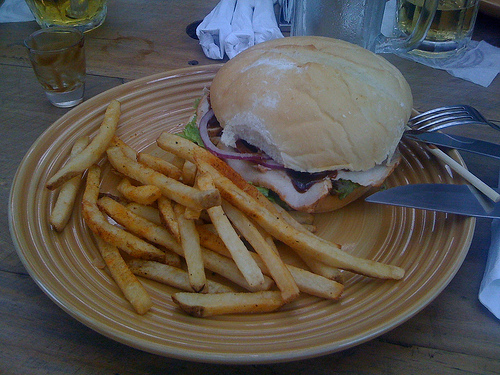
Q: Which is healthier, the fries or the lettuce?
A: The lettuce is healthier than the fries.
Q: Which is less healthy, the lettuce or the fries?
A: The fries is less healthy than the lettuce.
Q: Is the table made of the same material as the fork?
A: No, the table is made of wood and the fork is made of metal.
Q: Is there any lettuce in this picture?
A: Yes, there is lettuce.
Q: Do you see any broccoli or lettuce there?
A: Yes, there is lettuce.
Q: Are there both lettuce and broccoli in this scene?
A: No, there is lettuce but no broccoli.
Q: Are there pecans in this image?
A: No, there are no pecans.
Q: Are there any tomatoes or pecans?
A: No, there are no pecans or tomatoes.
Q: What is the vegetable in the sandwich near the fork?
A: The vegetable is lettuce.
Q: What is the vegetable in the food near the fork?
A: The vegetable is lettuce.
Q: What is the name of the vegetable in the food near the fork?
A: The vegetable is lettuce.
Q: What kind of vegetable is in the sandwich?
A: The vegetable is lettuce.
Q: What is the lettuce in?
A: The lettuce is in the sandwich.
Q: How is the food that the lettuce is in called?
A: The food is a sandwich.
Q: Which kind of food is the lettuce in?
A: The lettuce is in the sandwich.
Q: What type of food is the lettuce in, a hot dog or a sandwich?
A: The lettuce is in a sandwich.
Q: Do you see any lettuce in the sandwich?
A: Yes, there is lettuce in the sandwich.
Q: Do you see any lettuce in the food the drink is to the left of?
A: Yes, there is lettuce in the sandwich.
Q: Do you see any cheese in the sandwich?
A: No, there is lettuce in the sandwich.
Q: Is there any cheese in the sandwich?
A: No, there is lettuce in the sandwich.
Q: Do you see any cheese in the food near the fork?
A: No, there is lettuce in the sandwich.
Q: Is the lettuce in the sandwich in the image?
A: Yes, the lettuce is in the sandwich.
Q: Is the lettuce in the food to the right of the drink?
A: Yes, the lettuce is in the sandwich.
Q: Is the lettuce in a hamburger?
A: No, the lettuce is in the sandwich.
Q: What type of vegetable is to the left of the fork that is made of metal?
A: The vegetable is lettuce.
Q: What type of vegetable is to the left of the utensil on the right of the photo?
A: The vegetable is lettuce.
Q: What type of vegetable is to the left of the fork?
A: The vegetable is lettuce.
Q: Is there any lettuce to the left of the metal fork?
A: Yes, there is lettuce to the left of the fork.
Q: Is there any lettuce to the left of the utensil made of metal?
A: Yes, there is lettuce to the left of the fork.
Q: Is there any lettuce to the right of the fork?
A: No, the lettuce is to the left of the fork.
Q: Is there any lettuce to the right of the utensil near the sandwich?
A: No, the lettuce is to the left of the fork.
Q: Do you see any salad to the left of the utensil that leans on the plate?
A: No, there is lettuce to the left of the fork.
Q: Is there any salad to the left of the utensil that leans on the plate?
A: No, there is lettuce to the left of the fork.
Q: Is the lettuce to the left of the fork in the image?
A: Yes, the lettuce is to the left of the fork.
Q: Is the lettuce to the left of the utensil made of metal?
A: Yes, the lettuce is to the left of the fork.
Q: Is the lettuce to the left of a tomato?
A: No, the lettuce is to the left of the fork.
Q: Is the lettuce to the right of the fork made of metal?
A: No, the lettuce is to the left of the fork.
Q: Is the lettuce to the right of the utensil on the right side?
A: No, the lettuce is to the left of the fork.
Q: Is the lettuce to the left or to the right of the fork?
A: The lettuce is to the left of the fork.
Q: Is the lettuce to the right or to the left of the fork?
A: The lettuce is to the left of the fork.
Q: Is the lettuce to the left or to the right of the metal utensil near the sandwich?
A: The lettuce is to the left of the fork.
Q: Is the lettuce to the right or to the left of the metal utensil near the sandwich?
A: The lettuce is to the left of the fork.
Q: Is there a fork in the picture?
A: Yes, there is a fork.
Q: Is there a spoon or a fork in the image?
A: Yes, there is a fork.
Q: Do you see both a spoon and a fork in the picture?
A: No, there is a fork but no spoons.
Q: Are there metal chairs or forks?
A: Yes, there is a metal fork.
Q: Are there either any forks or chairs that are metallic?
A: Yes, the fork is metallic.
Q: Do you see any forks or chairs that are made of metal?
A: Yes, the fork is made of metal.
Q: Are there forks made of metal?
A: Yes, there is a fork that is made of metal.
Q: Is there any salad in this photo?
A: No, there is no salad.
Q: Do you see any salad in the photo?
A: No, there is no salad.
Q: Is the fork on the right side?
A: Yes, the fork is on the right of the image.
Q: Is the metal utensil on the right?
A: Yes, the fork is on the right of the image.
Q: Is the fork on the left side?
A: No, the fork is on the right of the image.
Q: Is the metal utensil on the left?
A: No, the fork is on the right of the image.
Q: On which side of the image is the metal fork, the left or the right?
A: The fork is on the right of the image.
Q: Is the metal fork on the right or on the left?
A: The fork is on the right of the image.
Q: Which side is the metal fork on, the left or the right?
A: The fork is on the right of the image.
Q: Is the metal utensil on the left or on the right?
A: The fork is on the right of the image.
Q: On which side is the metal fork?
A: The fork is on the right of the image.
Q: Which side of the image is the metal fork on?
A: The fork is on the right of the image.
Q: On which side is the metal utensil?
A: The fork is on the right of the image.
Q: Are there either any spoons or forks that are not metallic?
A: No, there is a fork but it is metallic.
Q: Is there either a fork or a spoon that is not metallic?
A: No, there is a fork but it is metallic.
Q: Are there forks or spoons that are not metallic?
A: No, there is a fork but it is metallic.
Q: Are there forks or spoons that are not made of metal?
A: No, there is a fork but it is made of metal.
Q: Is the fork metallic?
A: Yes, the fork is metallic.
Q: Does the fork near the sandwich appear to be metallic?
A: Yes, the fork is metallic.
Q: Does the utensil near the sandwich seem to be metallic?
A: Yes, the fork is metallic.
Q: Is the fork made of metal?
A: Yes, the fork is made of metal.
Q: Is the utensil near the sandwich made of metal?
A: Yes, the fork is made of metal.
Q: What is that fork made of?
A: The fork is made of metal.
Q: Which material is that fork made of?
A: The fork is made of metal.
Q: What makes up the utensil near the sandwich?
A: The fork is made of metal.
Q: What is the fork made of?
A: The fork is made of metal.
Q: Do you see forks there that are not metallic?
A: No, there is a fork but it is metallic.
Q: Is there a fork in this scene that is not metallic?
A: No, there is a fork but it is metallic.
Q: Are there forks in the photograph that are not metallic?
A: No, there is a fork but it is metallic.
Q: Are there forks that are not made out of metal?
A: No, there is a fork but it is made of metal.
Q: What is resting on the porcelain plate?
A: The fork is resting on the plate.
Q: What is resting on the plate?
A: The fork is resting on the plate.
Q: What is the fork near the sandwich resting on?
A: The fork is resting on the plate.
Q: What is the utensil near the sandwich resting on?
A: The fork is resting on the plate.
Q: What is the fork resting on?
A: The fork is resting on the plate.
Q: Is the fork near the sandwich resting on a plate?
A: Yes, the fork is resting on a plate.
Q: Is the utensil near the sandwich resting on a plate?
A: Yes, the fork is resting on a plate.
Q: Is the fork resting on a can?
A: No, the fork is resting on a plate.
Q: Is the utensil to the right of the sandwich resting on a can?
A: No, the fork is resting on a plate.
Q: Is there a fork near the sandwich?
A: Yes, there is a fork near the sandwich.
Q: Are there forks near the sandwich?
A: Yes, there is a fork near the sandwich.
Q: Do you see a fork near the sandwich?
A: Yes, there is a fork near the sandwich.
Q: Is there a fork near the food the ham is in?
A: Yes, there is a fork near the sandwich.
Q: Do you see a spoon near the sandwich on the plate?
A: No, there is a fork near the sandwich.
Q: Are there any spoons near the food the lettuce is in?
A: No, there is a fork near the sandwich.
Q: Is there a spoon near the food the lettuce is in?
A: No, there is a fork near the sandwich.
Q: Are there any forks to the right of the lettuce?
A: Yes, there is a fork to the right of the lettuce.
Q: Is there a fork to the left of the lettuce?
A: No, the fork is to the right of the lettuce.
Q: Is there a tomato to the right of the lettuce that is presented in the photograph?
A: No, there is a fork to the right of the lettuce.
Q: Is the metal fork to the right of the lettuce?
A: Yes, the fork is to the right of the lettuce.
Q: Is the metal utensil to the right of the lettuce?
A: Yes, the fork is to the right of the lettuce.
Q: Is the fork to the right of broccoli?
A: No, the fork is to the right of the lettuce.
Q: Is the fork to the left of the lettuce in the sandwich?
A: No, the fork is to the right of the lettuce.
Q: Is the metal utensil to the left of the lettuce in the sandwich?
A: No, the fork is to the right of the lettuce.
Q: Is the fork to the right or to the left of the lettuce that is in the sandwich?
A: The fork is to the right of the lettuce.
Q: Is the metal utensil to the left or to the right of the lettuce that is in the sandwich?
A: The fork is to the right of the lettuce.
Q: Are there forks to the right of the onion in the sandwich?
A: Yes, there is a fork to the right of the onion.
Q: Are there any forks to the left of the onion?
A: No, the fork is to the right of the onion.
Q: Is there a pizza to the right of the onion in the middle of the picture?
A: No, there is a fork to the right of the onion.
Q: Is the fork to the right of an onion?
A: Yes, the fork is to the right of an onion.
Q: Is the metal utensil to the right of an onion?
A: Yes, the fork is to the right of an onion.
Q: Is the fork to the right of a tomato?
A: No, the fork is to the right of an onion.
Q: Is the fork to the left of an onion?
A: No, the fork is to the right of an onion.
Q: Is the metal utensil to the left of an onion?
A: No, the fork is to the right of an onion.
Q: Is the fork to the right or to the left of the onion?
A: The fork is to the right of the onion.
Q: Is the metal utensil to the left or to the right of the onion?
A: The fork is to the right of the onion.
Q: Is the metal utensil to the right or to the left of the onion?
A: The fork is to the right of the onion.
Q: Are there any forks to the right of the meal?
A: Yes, there is a fork to the right of the meal.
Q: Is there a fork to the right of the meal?
A: Yes, there is a fork to the right of the meal.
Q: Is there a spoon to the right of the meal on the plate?
A: No, there is a fork to the right of the meal.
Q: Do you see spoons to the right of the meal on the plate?
A: No, there is a fork to the right of the meal.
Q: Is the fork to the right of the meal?
A: Yes, the fork is to the right of the meal.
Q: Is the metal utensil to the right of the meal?
A: Yes, the fork is to the right of the meal.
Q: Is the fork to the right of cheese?
A: No, the fork is to the right of the meal.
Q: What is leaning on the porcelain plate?
A: The fork is leaning on the plate.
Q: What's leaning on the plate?
A: The fork is leaning on the plate.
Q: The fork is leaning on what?
A: The fork is leaning on the plate.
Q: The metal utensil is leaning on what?
A: The fork is leaning on the plate.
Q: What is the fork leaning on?
A: The fork is leaning on the plate.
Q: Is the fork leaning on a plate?
A: Yes, the fork is leaning on a plate.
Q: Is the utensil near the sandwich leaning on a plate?
A: Yes, the fork is leaning on a plate.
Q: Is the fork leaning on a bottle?
A: No, the fork is leaning on a plate.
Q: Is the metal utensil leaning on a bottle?
A: No, the fork is leaning on a plate.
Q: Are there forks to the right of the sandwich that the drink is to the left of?
A: Yes, there is a fork to the right of the sandwich.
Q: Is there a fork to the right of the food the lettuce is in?
A: Yes, there is a fork to the right of the sandwich.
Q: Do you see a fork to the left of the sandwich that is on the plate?
A: No, the fork is to the right of the sandwich.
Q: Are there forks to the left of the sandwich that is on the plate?
A: No, the fork is to the right of the sandwich.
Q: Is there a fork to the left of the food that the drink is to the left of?
A: No, the fork is to the right of the sandwich.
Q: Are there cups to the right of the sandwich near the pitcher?
A: No, there is a fork to the right of the sandwich.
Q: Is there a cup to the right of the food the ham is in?
A: No, there is a fork to the right of the sandwich.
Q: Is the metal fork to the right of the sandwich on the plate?
A: Yes, the fork is to the right of the sandwich.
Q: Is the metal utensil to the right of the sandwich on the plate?
A: Yes, the fork is to the right of the sandwich.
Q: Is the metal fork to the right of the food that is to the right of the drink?
A: Yes, the fork is to the right of the sandwich.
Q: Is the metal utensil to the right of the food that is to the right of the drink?
A: Yes, the fork is to the right of the sandwich.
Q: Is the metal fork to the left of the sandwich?
A: No, the fork is to the right of the sandwich.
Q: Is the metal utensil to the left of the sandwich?
A: No, the fork is to the right of the sandwich.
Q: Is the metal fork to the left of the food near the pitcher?
A: No, the fork is to the right of the sandwich.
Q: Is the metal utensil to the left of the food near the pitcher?
A: No, the fork is to the right of the sandwich.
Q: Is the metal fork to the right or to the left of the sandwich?
A: The fork is to the right of the sandwich.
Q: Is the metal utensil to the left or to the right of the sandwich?
A: The fork is to the right of the sandwich.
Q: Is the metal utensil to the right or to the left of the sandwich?
A: The fork is to the right of the sandwich.